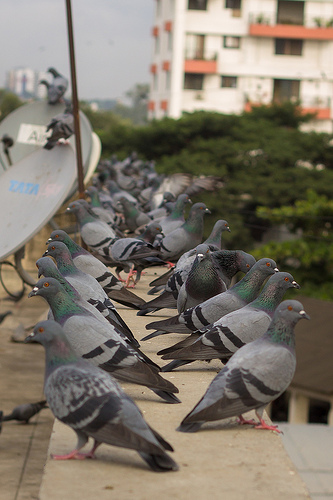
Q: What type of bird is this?
A: A grey black and green pigeon.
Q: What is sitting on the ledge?
A: A grey black and green pigeon.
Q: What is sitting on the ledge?
A: A grey black and green pigeon.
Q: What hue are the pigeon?
A: Grey black and green.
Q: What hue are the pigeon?
A: Grey black and green.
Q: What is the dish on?
A: Roof.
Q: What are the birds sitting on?
A: Roof.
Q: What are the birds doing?
A: Standing.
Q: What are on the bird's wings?
A: Stripes.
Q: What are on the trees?
A: Green leaves.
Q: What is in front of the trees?
A: Power lines.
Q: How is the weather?
A: Overcast.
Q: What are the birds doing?
A: Standing on a ledge.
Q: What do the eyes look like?
A: Red.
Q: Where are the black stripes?
A: On the birds wings.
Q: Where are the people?
A: There are no people.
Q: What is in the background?
A: Buildings.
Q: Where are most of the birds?
A: On the ledge.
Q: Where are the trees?
A: Below the birds.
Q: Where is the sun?
A: Behind the clouds.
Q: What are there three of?
A: Satellite dish.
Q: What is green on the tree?
A: Leaves.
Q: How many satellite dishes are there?
A: Two.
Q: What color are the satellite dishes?
A: Gray and white.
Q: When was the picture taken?
A: Daytime.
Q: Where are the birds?
A: On the ledge.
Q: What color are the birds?
A: Gray and black.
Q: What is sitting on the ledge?
A: The birds.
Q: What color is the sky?
A: Gray.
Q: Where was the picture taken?
A: In the city on a concrete wall.